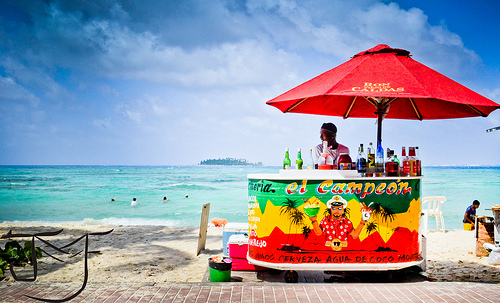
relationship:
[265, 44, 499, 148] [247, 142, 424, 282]
umbrella at a beach bar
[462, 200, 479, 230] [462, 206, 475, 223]
man wearing a shirt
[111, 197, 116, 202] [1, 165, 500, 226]
swimmer in water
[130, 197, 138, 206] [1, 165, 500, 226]
swimmer in water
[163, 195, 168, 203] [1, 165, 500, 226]
swimmer in water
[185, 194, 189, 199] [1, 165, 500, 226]
swimmer in water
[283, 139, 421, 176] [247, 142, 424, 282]
bottles on beach bar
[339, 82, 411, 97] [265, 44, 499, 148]
logo on umbrella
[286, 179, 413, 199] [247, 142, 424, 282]
company on beach bar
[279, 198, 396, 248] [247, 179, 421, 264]
trees on design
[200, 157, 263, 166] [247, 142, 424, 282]
island far from beach bar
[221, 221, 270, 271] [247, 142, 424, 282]
supplies behind beach bar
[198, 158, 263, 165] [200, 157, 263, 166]
trees on island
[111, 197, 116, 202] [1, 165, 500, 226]
swimmer sticking out of water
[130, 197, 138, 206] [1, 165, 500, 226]
swimmer sticking out of water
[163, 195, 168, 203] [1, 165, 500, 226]
swimmer sticking out of water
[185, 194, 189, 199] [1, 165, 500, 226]
swimmer sticking out of water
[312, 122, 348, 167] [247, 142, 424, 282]
man behind beach bar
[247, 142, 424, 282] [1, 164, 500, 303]
beach bar at beach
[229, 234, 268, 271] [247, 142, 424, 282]
cooler next to beach bar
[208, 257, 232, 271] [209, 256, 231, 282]
black liner in trash can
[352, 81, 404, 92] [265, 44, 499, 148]
writing on umbrella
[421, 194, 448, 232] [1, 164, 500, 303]
chair at beach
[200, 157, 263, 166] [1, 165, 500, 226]
island in water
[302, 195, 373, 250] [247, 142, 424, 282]
picture on beach bar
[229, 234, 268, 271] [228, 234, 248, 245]
cooler has a lid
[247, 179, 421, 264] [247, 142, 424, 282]
design on beach bar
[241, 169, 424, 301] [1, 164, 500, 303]
bar at beach